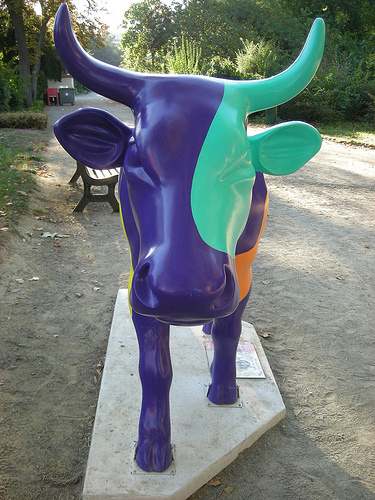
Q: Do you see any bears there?
A: No, there are no bears.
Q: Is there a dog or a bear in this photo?
A: No, there are no bears or dogs.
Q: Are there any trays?
A: No, there are no trays.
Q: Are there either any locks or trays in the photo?
A: No, there are no trays or locks.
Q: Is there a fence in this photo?
A: No, there are no fences.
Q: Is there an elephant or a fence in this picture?
A: No, there are no fences or elephants.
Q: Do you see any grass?
A: Yes, there is grass.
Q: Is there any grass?
A: Yes, there is grass.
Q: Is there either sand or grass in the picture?
A: Yes, there is grass.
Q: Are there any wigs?
A: No, there are no wigs.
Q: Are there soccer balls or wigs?
A: No, there are no wigs or soccer balls.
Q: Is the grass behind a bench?
A: Yes, the grass is behind a bench.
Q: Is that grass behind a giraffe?
A: No, the grass is behind a bench.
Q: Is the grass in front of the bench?
A: No, the grass is behind the bench.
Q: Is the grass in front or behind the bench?
A: The grass is behind the bench.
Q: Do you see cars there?
A: No, there are no cars.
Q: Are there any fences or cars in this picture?
A: No, there are no cars or fences.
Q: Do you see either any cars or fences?
A: No, there are no cars or fences.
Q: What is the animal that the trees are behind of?
A: The animal is a bull.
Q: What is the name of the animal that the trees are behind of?
A: The animal is a bull.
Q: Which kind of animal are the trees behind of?
A: The trees are behind the bull.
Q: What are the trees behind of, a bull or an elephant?
A: The trees are behind a bull.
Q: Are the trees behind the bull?
A: Yes, the trees are behind the bull.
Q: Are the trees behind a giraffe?
A: No, the trees are behind the bull.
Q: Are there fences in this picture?
A: No, there are no fences.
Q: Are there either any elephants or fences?
A: No, there are no fences or elephants.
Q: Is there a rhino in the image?
A: No, there are no rhinos.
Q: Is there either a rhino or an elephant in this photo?
A: No, there are no rhinos or elephants.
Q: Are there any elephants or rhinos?
A: No, there are no rhinos or elephants.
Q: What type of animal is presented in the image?
A: The animal is a bull.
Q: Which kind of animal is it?
A: The animal is a bull.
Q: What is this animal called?
A: This is a bull.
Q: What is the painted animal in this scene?
A: The animal is a bull.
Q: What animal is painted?
A: The animal is a bull.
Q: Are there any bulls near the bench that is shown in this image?
A: Yes, there is a bull near the bench.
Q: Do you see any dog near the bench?
A: No, there is a bull near the bench.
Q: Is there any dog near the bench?
A: No, there is a bull near the bench.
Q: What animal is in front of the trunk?
A: The bull is in front of the trunk.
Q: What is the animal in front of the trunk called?
A: The animal is a bull.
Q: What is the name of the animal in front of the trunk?
A: The animal is a bull.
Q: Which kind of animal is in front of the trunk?
A: The animal is a bull.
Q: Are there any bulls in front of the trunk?
A: Yes, there is a bull in front of the trunk.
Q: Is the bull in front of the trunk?
A: Yes, the bull is in front of the trunk.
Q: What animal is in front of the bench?
A: The bull is in front of the bench.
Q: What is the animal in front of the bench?
A: The animal is a bull.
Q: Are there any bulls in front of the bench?
A: Yes, there is a bull in front of the bench.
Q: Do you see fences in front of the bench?
A: No, there is a bull in front of the bench.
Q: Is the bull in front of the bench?
A: Yes, the bull is in front of the bench.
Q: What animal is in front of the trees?
A: The bull is in front of the trees.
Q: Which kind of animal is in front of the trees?
A: The animal is a bull.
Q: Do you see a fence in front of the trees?
A: No, there is a bull in front of the trees.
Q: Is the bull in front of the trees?
A: Yes, the bull is in front of the trees.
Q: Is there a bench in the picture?
A: Yes, there is a bench.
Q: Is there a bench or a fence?
A: Yes, there is a bench.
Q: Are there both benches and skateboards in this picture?
A: No, there is a bench but no skateboards.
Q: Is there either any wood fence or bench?
A: Yes, there is a wood bench.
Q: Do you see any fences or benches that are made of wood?
A: Yes, the bench is made of wood.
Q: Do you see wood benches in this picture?
A: Yes, there is a wood bench.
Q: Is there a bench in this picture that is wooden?
A: Yes, there is a bench that is wooden.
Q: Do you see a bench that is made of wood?
A: Yes, there is a bench that is made of wood.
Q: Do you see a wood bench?
A: Yes, there is a bench that is made of wood.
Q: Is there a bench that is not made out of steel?
A: Yes, there is a bench that is made of wood.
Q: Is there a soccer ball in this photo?
A: No, there are no soccer balls.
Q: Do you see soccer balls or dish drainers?
A: No, there are no soccer balls or dish drainers.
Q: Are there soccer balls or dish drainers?
A: No, there are no soccer balls or dish drainers.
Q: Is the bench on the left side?
A: Yes, the bench is on the left of the image.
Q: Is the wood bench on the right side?
A: No, the bench is on the left of the image.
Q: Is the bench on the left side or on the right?
A: The bench is on the left of the image.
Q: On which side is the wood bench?
A: The bench is on the left of the image.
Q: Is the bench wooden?
A: Yes, the bench is wooden.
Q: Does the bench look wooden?
A: Yes, the bench is wooden.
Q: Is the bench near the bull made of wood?
A: Yes, the bench is made of wood.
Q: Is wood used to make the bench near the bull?
A: Yes, the bench is made of wood.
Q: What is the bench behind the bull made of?
A: The bench is made of wood.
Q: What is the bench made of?
A: The bench is made of wood.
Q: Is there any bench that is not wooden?
A: No, there is a bench but it is wooden.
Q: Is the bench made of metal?
A: No, the bench is made of wood.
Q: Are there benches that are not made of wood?
A: No, there is a bench but it is made of wood.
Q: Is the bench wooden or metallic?
A: The bench is wooden.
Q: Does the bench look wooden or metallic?
A: The bench is wooden.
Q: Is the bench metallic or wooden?
A: The bench is wooden.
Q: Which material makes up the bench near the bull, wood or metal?
A: The bench is made of wood.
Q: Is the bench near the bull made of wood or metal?
A: The bench is made of wood.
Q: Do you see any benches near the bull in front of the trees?
A: Yes, there is a bench near the bull.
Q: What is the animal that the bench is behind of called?
A: The animal is a bull.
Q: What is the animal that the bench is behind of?
A: The animal is a bull.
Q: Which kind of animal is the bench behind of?
A: The bench is behind the bull.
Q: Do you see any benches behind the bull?
A: Yes, there is a bench behind the bull.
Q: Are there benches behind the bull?
A: Yes, there is a bench behind the bull.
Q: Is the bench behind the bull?
A: Yes, the bench is behind the bull.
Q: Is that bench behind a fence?
A: No, the bench is behind the bull.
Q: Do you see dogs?
A: No, there are no dogs.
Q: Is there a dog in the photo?
A: No, there are no dogs.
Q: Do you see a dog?
A: No, there are no dogs.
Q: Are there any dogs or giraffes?
A: No, there are no dogs or giraffes.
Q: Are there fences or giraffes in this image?
A: No, there are no fences or giraffes.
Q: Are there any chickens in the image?
A: No, there are no chickens.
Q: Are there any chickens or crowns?
A: No, there are no chickens or crowns.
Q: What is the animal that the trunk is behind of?
A: The animal is a bull.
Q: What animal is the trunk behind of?
A: The trunk is behind the bull.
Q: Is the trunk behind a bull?
A: Yes, the trunk is behind a bull.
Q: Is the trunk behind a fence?
A: No, the trunk is behind a bull.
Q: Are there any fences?
A: No, there are no fences.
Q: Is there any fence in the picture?
A: No, there are no fences.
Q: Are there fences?
A: No, there are no fences.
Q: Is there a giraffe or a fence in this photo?
A: No, there are no fences or giraffes.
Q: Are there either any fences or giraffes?
A: No, there are no fences or giraffes.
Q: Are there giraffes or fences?
A: No, there are no fences or giraffes.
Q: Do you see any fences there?
A: No, there are no fences.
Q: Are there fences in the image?
A: No, there are no fences.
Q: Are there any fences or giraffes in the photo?
A: No, there are no fences or giraffes.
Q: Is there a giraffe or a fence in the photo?
A: No, there are no fences or giraffes.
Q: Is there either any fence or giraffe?
A: No, there are no fences or giraffes.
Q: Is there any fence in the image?
A: No, there are no fences.